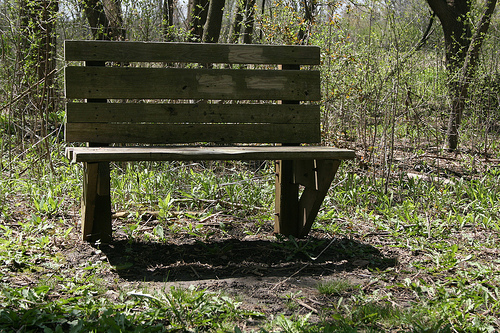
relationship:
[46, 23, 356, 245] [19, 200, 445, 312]
bench on dirt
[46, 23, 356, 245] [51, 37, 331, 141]
bench has planks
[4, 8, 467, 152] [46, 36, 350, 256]
trees behind bench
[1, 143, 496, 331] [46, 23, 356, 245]
plants grow under bench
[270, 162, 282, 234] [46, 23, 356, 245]
bolts in bench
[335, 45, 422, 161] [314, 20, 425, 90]
plants with leaves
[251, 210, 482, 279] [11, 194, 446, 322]
sticks lay on ground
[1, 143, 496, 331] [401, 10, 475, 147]
plants underneath trees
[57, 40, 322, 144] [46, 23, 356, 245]
planks on bench